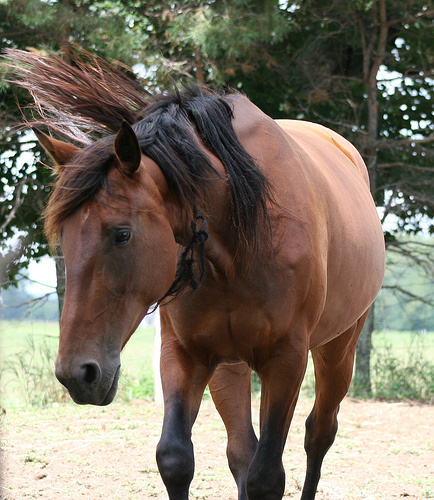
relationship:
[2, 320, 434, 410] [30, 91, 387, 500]
grass behind horse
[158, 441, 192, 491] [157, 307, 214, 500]
knee on leg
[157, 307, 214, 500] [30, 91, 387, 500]
leg of horse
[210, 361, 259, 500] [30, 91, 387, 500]
leg of horse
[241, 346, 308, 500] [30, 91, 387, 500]
leg of horse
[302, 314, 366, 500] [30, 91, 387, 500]
leg of horse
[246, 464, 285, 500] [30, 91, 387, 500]
knee of horse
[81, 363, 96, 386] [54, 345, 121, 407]
nostril on snout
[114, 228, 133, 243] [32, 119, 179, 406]
eye on head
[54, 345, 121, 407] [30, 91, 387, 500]
snout of horse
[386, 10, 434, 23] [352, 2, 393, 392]
branch of tree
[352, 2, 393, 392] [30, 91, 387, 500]
tree behind horse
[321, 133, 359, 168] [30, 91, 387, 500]
ropw around horse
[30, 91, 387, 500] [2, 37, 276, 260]
horse flicking its mane